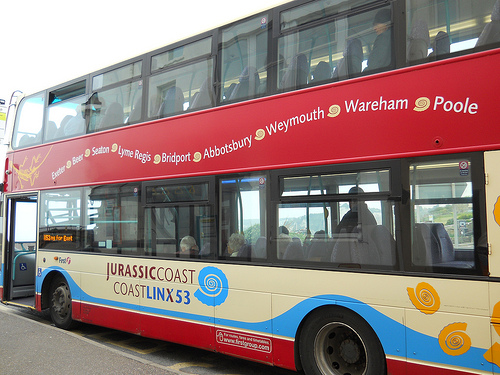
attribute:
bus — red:
[0, 63, 444, 194]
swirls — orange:
[405, 280, 473, 358]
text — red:
[81, 250, 222, 320]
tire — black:
[46, 271, 77, 326]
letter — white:
[343, 96, 358, 116]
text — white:
[51, 94, 478, 177]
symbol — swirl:
[178, 263, 238, 323]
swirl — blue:
[193, 265, 228, 307]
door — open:
[1, 194, 38, 315]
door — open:
[2, 190, 39, 310]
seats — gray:
[410, 222, 478, 281]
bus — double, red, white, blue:
[0, 1, 497, 373]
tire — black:
[45, 278, 86, 330]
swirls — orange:
[409, 279, 440, 316]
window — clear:
[41, 147, 493, 280]